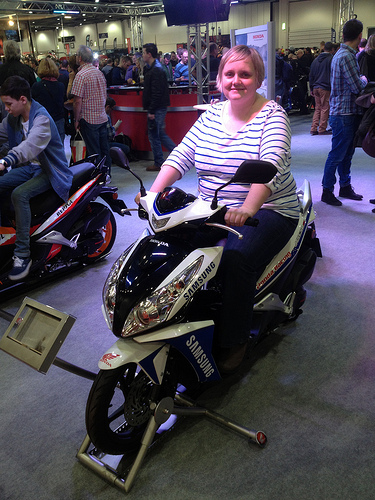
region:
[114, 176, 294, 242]
hands gripped around handlebars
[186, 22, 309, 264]
woman smiling as she poses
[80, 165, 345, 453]
modern and aerodynamic design of motorscooter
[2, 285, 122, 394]
panel with information attached to stand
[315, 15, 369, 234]
man in plaid shirt looking to his left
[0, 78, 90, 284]
boy seated on red, white and black scooter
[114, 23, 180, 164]
man passing in front of curved partition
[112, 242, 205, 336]
headlights inside long narrowing panel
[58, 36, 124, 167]
man in red and white checkered shirt carrying a tote bag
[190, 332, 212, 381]
this is a samsung brand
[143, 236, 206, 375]
samsung made bikes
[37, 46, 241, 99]
people attending a samsung workshop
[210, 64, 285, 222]
a white woman on a bike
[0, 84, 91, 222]
a boy on a bike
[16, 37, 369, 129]
many people on a workshop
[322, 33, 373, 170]
a guy is on the image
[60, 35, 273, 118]
a very generous turn up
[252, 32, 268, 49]
honda brand sign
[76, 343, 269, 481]
motorcycle wheel lock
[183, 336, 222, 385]
white samsung logo on black paint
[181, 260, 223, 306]
black samsung logo on white paint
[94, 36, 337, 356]
lady tring out new SAMSUNG bike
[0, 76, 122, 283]
man trying out new bike on sales floor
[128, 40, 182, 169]
man in black jacket and jeans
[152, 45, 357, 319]
blond woman in white and blue striped shirt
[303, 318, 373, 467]
grey carpet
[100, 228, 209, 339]
SAMSUNG headlights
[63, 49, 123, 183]
man carrying a bag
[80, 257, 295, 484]
motorcycle is a Samsung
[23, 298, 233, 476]
cycle has a break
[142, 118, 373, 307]
woman is on a bike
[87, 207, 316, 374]
samsung bike is new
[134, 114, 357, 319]
woman is sitting on motorcycle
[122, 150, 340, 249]
woman knows how to drive bike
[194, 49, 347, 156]
woman looks happy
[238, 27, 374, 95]
woman is at a bike show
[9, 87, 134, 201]
man is riding motorcycle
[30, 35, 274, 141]
large event is going on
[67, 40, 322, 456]
a woman sitting on a bike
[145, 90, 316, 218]
woman is wearing a striped shirt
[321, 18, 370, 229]
a man is wearing blue plaid shirt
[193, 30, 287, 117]
woman has short hair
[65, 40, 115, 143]
man is wearing red plaid shirt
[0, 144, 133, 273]
bike is orange and black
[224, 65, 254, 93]
woman is smiling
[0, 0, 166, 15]
railings in the background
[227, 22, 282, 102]
a sign behind the woman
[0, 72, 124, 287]
a kid sitting on bike